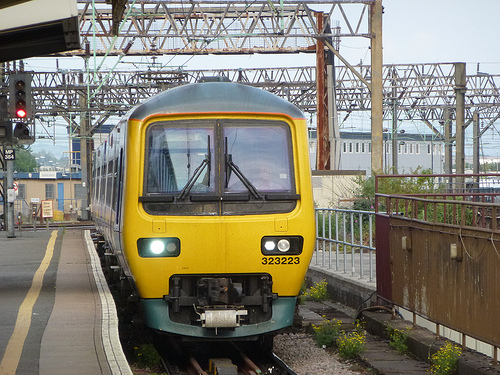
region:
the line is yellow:
[17, 320, 24, 329]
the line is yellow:
[19, 294, 38, 317]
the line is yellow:
[33, 295, 36, 300]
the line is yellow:
[22, 303, 26, 305]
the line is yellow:
[19, 303, 30, 317]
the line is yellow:
[13, 310, 49, 338]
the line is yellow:
[19, 318, 30, 334]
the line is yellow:
[22, 325, 26, 328]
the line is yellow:
[17, 331, 25, 346]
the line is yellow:
[28, 313, 33, 314]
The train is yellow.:
[106, 81, 308, 345]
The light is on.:
[125, 231, 165, 273]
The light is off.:
[170, 231, 187, 266]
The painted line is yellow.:
[6, 219, 70, 373]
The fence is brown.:
[379, 196, 483, 324]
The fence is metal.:
[312, 193, 377, 287]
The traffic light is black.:
[7, 69, 32, 129]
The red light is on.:
[13, 105, 25, 115]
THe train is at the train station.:
[42, 98, 293, 366]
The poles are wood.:
[363, 2, 395, 194]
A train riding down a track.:
[91, 82, 331, 355]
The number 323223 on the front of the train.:
[260, 255, 302, 266]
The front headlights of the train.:
[135, 235, 307, 255]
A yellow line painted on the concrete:
[0, 226, 65, 371]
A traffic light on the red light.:
[10, 66, 35, 126]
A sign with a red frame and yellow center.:
[38, 195, 53, 223]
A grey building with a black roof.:
[307, 126, 445, 173]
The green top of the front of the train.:
[130, 78, 310, 116]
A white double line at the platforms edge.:
[82, 225, 123, 372]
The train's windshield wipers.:
[177, 131, 263, 208]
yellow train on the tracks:
[98, 75, 365, 327]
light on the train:
[129, 231, 197, 281]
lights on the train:
[256, 232, 314, 264]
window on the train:
[121, 102, 318, 218]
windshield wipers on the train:
[175, 140, 269, 210]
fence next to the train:
[318, 204, 381, 289]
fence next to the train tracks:
[373, 200, 498, 352]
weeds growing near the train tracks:
[315, 312, 376, 359]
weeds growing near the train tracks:
[423, 341, 465, 372]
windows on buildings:
[344, 134, 376, 154]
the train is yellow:
[131, 131, 232, 320]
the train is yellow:
[188, 169, 296, 287]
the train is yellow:
[159, 204, 197, 254]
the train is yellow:
[171, 179, 228, 236]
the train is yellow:
[182, 171, 211, 201]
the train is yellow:
[167, 231, 222, 285]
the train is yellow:
[165, 207, 215, 247]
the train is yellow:
[204, 194, 247, 257]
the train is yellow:
[167, 214, 252, 304]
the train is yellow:
[176, 214, 267, 359]